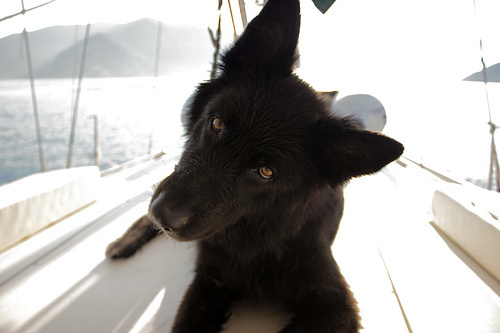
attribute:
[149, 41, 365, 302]
dog — black, laying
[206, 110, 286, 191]
eyes — brown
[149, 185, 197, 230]
nose — black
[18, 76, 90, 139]
water — blue, far, calm, shining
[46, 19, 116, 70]
mountains — far away, far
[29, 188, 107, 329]
boat — white, metal, light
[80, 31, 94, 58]
pole — skinny